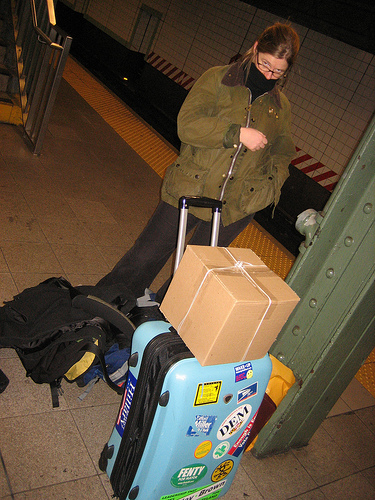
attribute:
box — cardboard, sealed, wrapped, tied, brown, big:
[154, 238, 302, 370]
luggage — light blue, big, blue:
[93, 308, 275, 500]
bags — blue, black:
[2, 275, 110, 390]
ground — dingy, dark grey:
[1, 28, 374, 499]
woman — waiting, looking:
[82, 20, 308, 311]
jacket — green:
[155, 54, 296, 229]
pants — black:
[82, 179, 256, 319]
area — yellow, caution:
[42, 34, 296, 291]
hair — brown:
[235, 22, 299, 95]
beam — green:
[252, 98, 375, 460]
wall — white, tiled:
[60, 2, 373, 194]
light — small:
[121, 72, 129, 83]